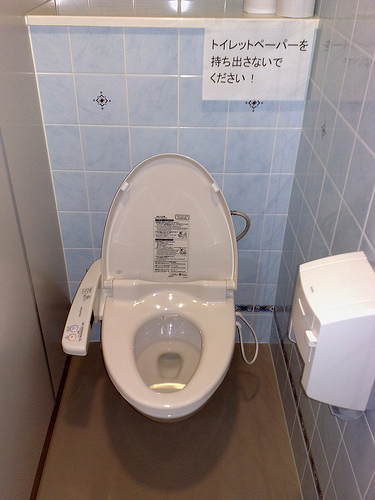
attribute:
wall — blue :
[26, 29, 317, 349]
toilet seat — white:
[101, 286, 240, 424]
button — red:
[67, 333, 76, 339]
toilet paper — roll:
[277, 2, 320, 20]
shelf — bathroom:
[23, 4, 327, 55]